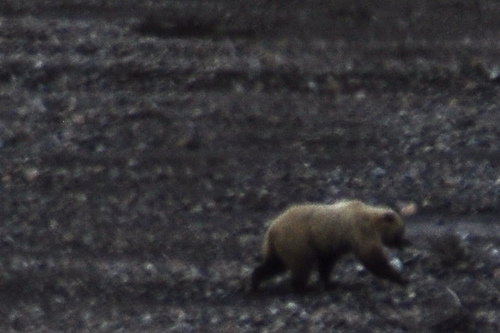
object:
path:
[0, 240, 498, 332]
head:
[377, 205, 413, 252]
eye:
[393, 230, 403, 237]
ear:
[380, 210, 401, 222]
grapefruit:
[242, 196, 411, 296]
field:
[0, 0, 500, 333]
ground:
[3, 3, 497, 330]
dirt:
[2, 1, 499, 331]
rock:
[388, 258, 405, 273]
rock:
[354, 264, 364, 272]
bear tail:
[261, 228, 274, 266]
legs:
[274, 243, 316, 294]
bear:
[244, 199, 413, 296]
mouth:
[398, 243, 411, 250]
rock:
[145, 263, 153, 269]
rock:
[284, 302, 297, 311]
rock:
[142, 314, 153, 322]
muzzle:
[398, 233, 412, 246]